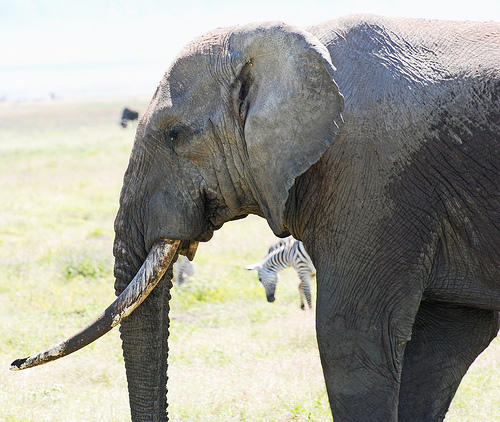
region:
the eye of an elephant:
[147, 113, 194, 153]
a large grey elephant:
[6, 5, 498, 387]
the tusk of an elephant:
[0, 261, 173, 386]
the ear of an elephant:
[217, 44, 361, 219]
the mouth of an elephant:
[178, 196, 242, 243]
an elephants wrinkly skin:
[383, 123, 465, 232]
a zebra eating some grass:
[237, 239, 317, 318]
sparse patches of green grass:
[20, 205, 99, 296]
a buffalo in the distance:
[107, 98, 144, 134]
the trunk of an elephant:
[90, 273, 195, 418]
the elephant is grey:
[147, 30, 492, 412]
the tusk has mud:
[65, 267, 151, 351]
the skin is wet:
[381, 130, 497, 236]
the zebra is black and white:
[260, 241, 308, 313]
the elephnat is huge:
[110, 21, 489, 418]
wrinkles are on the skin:
[386, 139, 450, 239]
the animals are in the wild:
[8, 34, 493, 416]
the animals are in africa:
[8, 22, 496, 417]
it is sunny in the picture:
[8, 8, 466, 419]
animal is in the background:
[109, 107, 152, 132]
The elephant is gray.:
[13, 35, 497, 409]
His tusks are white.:
[0, 233, 182, 399]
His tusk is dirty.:
[8, 228, 171, 420]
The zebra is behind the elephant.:
[234, 217, 329, 322]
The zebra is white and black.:
[234, 234, 329, 321]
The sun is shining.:
[0, 9, 495, 413]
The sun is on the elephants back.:
[3, 2, 494, 225]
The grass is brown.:
[2, 141, 310, 420]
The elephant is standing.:
[21, 28, 482, 413]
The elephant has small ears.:
[77, 6, 347, 268]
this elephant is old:
[16, 21, 358, 401]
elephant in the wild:
[14, 14, 409, 416]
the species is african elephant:
[16, 5, 334, 395]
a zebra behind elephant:
[238, 239, 320, 324]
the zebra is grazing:
[233, 243, 325, 317]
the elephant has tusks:
[21, 23, 265, 370]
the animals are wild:
[13, 12, 481, 402]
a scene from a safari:
[13, 18, 466, 420]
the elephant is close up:
[20, 19, 477, 414]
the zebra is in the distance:
[233, 235, 336, 345]